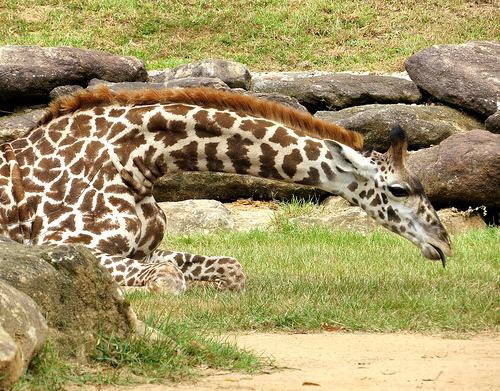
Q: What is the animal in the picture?
A: Giraffe.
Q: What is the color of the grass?
A: Green.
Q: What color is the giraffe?
A: Brown and white.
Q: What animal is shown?
A: A giraffe.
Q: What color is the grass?
A: Green.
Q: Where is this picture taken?
A: A zoo.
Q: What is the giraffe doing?
A: Eating.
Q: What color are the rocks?
A: Grey.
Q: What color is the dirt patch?
A: Brown.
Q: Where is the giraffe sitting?
A: On grass.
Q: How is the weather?
A: Clear.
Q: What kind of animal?
A: Giraffe.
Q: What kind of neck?
A: Long.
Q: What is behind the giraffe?
A: Rocks.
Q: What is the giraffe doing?
A: Sitting.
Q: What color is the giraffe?
A: Brown and white.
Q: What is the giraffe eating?
A: Grass.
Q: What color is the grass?
A: Green.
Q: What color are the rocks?
A: Brown and gray.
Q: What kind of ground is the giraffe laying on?
A: Grass.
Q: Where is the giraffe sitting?
A: On the ground.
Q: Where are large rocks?
A: Behind the giraffe.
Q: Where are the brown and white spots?
A: All over the giraffe's body.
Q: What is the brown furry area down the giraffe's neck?
A: The mane.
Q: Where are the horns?
A: On top of the giraffe's head.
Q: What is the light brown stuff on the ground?
A: Sand.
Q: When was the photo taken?
A: Daytime.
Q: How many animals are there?
A: 1.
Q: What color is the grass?
A: Green.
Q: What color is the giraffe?
A: Brown and white.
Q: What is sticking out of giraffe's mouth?
A: Tongue.